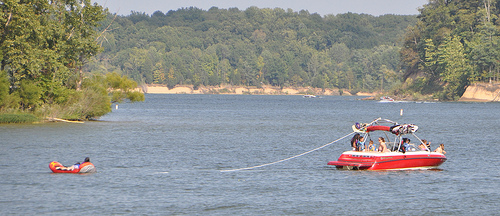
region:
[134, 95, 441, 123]
a large calm river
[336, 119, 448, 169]
the family on the boat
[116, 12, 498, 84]
a dense forest in the background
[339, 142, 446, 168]
a red boat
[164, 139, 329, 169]
a long white rope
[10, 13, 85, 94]
many tree branches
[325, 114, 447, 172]
several people enjoying a sunny day on the boat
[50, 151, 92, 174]
an object attached to the boat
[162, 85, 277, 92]
part of the dry terrain in the distance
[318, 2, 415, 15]
part of the sky in the distance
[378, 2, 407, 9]
this is the sky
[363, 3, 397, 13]
the sky is blue in color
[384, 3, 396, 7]
the sky has clouds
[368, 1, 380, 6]
the clouds are white in color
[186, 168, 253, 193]
this is the water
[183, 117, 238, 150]
the water is blue in color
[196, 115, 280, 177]
the water has ripples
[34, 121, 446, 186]
this is a boat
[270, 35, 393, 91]
these are the trees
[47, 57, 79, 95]
the leaves are green in color